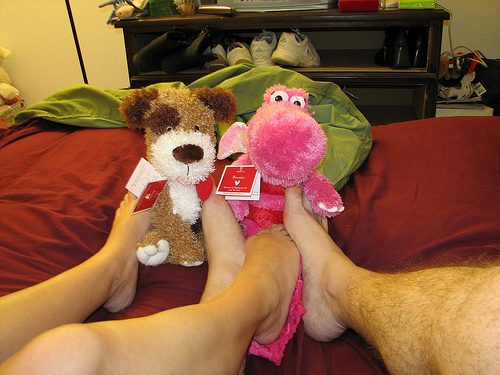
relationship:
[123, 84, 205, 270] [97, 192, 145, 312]
dog in front of foot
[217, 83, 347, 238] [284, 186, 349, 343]
stuffed animal in front of foot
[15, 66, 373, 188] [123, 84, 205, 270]
blanket behind dog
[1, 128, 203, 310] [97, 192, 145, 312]
comfortor beneath foot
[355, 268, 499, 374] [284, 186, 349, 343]
hair above foot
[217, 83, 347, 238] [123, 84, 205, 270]
stuffed animal next to dog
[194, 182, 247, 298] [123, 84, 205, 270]
foot in front of dog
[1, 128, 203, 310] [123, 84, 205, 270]
comfortor beneath dog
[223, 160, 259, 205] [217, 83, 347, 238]
tag beneath stuffed animal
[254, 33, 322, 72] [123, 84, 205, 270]
shoes are behind dog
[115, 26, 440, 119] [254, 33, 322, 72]
shelf holding shoes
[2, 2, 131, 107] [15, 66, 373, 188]
wall behind blanket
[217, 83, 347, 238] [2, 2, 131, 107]
stuffed animal in front of wall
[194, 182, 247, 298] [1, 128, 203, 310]
foot on comfortor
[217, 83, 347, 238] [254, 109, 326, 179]
stuffed animal has round nose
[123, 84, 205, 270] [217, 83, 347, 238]
dog next to stuffed animal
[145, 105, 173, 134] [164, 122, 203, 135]
spot above eyes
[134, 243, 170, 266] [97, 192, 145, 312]
dog's foot next to foot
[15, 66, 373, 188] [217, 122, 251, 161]
blanket behind wing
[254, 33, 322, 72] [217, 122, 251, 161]
shoes are behind wing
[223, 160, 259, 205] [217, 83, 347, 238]
tag in front of stuffed animal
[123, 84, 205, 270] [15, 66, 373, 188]
dog in front of blanket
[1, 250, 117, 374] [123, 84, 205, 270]
leg in front of dog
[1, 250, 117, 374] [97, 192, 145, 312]
leg attached to foot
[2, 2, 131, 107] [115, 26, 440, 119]
wall next to shelf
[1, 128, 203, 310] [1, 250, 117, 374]
comfortor beneath leg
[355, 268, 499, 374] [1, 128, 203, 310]
hair above comfortor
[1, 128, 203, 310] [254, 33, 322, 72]
comfortor in front of shoes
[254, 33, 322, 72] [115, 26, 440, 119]
shoes are above shelf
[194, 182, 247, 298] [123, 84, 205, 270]
foot touching dog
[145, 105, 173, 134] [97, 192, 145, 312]
spot above foot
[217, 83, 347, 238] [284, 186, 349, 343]
stuffed animal above foot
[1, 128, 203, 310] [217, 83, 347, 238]
comfortor beneath stuffed animal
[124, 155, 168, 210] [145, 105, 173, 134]
tag beneath spot